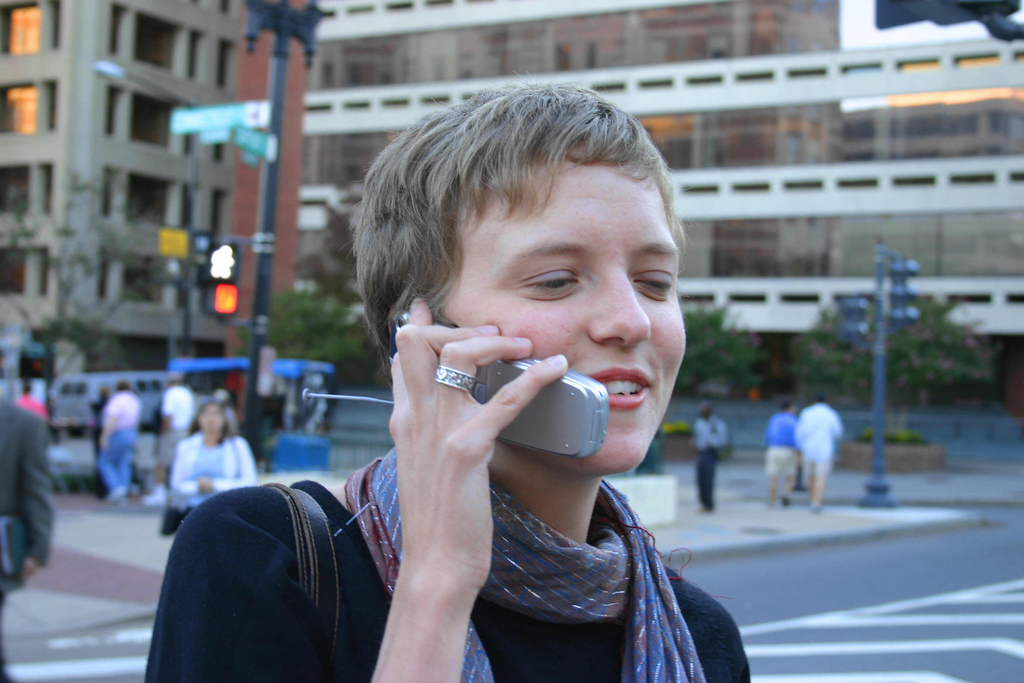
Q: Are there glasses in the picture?
A: No, there are no glasses.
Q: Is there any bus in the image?
A: Yes, there is a bus.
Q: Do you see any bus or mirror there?
A: Yes, there is a bus.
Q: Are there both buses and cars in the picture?
A: No, there is a bus but no cars.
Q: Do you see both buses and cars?
A: No, there is a bus but no cars.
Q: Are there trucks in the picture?
A: No, there are no trucks.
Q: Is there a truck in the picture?
A: No, there are no trucks.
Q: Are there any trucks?
A: No, there are no trucks.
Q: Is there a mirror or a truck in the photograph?
A: No, there are no trucks or mirrors.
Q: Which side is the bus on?
A: The bus is on the left of the image.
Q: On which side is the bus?
A: The bus is on the left of the image.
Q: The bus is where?
A: The bus is on the road.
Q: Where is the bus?
A: The bus is on the road.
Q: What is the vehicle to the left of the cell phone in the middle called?
A: The vehicle is a bus.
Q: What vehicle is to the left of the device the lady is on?
A: The vehicle is a bus.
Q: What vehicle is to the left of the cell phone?
A: The vehicle is a bus.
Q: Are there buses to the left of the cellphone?
A: Yes, there is a bus to the left of the cellphone.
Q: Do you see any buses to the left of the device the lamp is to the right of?
A: Yes, there is a bus to the left of the cellphone.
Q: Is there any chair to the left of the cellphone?
A: No, there is a bus to the left of the cellphone.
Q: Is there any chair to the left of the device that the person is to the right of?
A: No, there is a bus to the left of the cellphone.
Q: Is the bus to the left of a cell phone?
A: Yes, the bus is to the left of a cell phone.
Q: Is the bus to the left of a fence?
A: No, the bus is to the left of a cell phone.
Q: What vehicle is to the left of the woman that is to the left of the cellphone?
A: The vehicle is a bus.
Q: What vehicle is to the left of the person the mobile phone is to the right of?
A: The vehicle is a bus.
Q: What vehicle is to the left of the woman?
A: The vehicle is a bus.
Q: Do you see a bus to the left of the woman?
A: Yes, there is a bus to the left of the woman.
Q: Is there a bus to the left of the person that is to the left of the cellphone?
A: Yes, there is a bus to the left of the woman.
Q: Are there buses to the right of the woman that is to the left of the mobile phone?
A: No, the bus is to the left of the woman.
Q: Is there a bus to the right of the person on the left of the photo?
A: No, the bus is to the left of the woman.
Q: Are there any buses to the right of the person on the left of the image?
A: No, the bus is to the left of the woman.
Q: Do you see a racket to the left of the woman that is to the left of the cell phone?
A: No, there is a bus to the left of the woman.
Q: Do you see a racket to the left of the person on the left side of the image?
A: No, there is a bus to the left of the woman.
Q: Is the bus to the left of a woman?
A: Yes, the bus is to the left of a woman.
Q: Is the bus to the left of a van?
A: No, the bus is to the left of a woman.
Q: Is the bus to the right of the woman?
A: No, the bus is to the left of the woman.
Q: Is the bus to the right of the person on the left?
A: No, the bus is to the left of the woman.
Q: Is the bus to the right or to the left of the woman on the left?
A: The bus is to the left of the woman.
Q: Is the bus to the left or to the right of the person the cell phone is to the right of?
A: The bus is to the left of the woman.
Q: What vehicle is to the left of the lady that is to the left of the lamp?
A: The vehicle is a bus.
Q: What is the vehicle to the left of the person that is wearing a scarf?
A: The vehicle is a bus.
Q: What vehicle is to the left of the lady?
A: The vehicle is a bus.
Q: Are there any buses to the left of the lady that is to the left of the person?
A: Yes, there is a bus to the left of the lady.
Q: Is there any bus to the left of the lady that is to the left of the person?
A: Yes, there is a bus to the left of the lady.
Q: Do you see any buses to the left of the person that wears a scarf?
A: Yes, there is a bus to the left of the lady.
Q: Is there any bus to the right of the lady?
A: No, the bus is to the left of the lady.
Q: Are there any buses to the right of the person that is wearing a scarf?
A: No, the bus is to the left of the lady.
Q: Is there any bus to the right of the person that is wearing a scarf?
A: No, the bus is to the left of the lady.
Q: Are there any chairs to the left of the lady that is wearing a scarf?
A: No, there is a bus to the left of the lady.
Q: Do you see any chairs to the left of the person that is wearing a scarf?
A: No, there is a bus to the left of the lady.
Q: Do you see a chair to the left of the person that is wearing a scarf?
A: No, there is a bus to the left of the lady.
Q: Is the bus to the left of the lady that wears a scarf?
A: Yes, the bus is to the left of the lady.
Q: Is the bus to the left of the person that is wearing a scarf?
A: Yes, the bus is to the left of the lady.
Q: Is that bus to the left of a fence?
A: No, the bus is to the left of the lady.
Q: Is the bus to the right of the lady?
A: No, the bus is to the left of the lady.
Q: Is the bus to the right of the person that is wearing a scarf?
A: No, the bus is to the left of the lady.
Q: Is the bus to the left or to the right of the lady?
A: The bus is to the left of the lady.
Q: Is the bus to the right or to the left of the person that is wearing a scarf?
A: The bus is to the left of the lady.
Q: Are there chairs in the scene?
A: No, there are no chairs.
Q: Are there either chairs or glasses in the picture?
A: No, there are no chairs or glasses.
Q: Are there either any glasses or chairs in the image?
A: No, there are no chairs or glasses.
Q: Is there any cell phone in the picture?
A: Yes, there is a cell phone.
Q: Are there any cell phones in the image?
A: Yes, there is a cell phone.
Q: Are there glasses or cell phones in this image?
A: Yes, there is a cell phone.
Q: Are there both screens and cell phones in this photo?
A: No, there is a cell phone but no screens.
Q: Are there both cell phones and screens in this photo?
A: No, there is a cell phone but no screens.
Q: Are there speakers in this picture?
A: No, there are no speakers.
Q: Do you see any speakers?
A: No, there are no speakers.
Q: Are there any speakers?
A: No, there are no speakers.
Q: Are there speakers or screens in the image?
A: No, there are no speakers or screens.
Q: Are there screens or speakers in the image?
A: No, there are no speakers or screens.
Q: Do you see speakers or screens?
A: No, there are no speakers or screens.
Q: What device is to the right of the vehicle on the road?
A: The device is a cell phone.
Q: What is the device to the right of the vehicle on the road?
A: The device is a cell phone.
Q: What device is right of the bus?
A: The device is a cell phone.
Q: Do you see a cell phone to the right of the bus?
A: Yes, there is a cell phone to the right of the bus.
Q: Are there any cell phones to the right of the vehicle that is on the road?
A: Yes, there is a cell phone to the right of the bus.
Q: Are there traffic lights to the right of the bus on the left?
A: No, there is a cell phone to the right of the bus.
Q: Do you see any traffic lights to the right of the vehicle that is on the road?
A: No, there is a cell phone to the right of the bus.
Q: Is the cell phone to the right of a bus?
A: Yes, the cell phone is to the right of a bus.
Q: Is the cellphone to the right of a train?
A: No, the cellphone is to the right of a bus.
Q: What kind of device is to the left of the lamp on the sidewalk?
A: The device is a cell phone.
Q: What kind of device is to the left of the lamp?
A: The device is a cell phone.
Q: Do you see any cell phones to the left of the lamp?
A: Yes, there is a cell phone to the left of the lamp.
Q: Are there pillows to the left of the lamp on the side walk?
A: No, there is a cell phone to the left of the lamp.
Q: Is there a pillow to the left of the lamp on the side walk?
A: No, there is a cell phone to the left of the lamp.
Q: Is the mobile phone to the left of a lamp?
A: Yes, the mobile phone is to the left of a lamp.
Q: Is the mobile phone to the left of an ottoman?
A: No, the mobile phone is to the left of a lamp.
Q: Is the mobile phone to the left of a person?
A: Yes, the mobile phone is to the left of a person.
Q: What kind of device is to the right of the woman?
A: The device is a cell phone.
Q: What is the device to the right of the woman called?
A: The device is a cell phone.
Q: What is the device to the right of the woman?
A: The device is a cell phone.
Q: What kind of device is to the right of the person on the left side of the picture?
A: The device is a cell phone.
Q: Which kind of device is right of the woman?
A: The device is a cell phone.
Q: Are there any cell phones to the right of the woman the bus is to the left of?
A: Yes, there is a cell phone to the right of the woman.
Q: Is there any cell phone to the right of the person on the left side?
A: Yes, there is a cell phone to the right of the woman.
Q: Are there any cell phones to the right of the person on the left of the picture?
A: Yes, there is a cell phone to the right of the woman.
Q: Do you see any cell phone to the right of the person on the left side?
A: Yes, there is a cell phone to the right of the woman.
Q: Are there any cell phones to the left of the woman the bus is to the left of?
A: No, the cell phone is to the right of the woman.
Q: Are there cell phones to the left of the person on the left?
A: No, the cell phone is to the right of the woman.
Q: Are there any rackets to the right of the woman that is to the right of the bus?
A: No, there is a cell phone to the right of the woman.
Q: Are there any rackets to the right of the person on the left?
A: No, there is a cell phone to the right of the woman.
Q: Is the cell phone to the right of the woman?
A: Yes, the cell phone is to the right of the woman.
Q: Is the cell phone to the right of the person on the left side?
A: Yes, the cell phone is to the right of the woman.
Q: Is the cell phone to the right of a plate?
A: No, the cell phone is to the right of the woman.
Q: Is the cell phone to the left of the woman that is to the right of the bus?
A: No, the cell phone is to the right of the woman.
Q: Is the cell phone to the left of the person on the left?
A: No, the cell phone is to the right of the woman.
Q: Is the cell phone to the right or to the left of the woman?
A: The cell phone is to the right of the woman.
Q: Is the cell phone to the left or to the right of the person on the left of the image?
A: The cell phone is to the right of the woman.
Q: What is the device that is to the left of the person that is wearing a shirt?
A: The device is a cell phone.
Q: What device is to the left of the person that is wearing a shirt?
A: The device is a cell phone.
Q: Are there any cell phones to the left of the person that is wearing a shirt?
A: Yes, there is a cell phone to the left of the person.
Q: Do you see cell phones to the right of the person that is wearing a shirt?
A: No, the cell phone is to the left of the person.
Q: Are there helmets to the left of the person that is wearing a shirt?
A: No, there is a cell phone to the left of the person.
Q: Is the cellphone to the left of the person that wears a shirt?
A: Yes, the cellphone is to the left of the person.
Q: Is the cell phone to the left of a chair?
A: No, the cell phone is to the left of the person.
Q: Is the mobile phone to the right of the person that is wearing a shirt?
A: No, the mobile phone is to the left of the person.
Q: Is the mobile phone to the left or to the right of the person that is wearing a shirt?
A: The mobile phone is to the left of the person.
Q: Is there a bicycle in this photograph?
A: No, there are no bicycles.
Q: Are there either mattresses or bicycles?
A: No, there are no bicycles or mattresses.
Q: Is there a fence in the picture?
A: No, there are no fences.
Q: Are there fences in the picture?
A: No, there are no fences.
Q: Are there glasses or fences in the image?
A: No, there are no fences or glasses.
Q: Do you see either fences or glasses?
A: No, there are no fences or glasses.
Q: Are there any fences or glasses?
A: No, there are no fences or glasses.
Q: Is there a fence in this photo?
A: No, there are no fences.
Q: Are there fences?
A: No, there are no fences.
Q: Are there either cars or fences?
A: No, there are no fences or cars.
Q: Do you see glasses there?
A: No, there are no glasses.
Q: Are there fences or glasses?
A: No, there are no glasses or fences.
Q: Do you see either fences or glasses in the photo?
A: No, there are no glasses or fences.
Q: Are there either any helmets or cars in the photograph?
A: No, there are no cars or helmets.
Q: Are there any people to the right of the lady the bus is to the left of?
A: Yes, there is a person to the right of the lady.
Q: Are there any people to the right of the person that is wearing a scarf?
A: Yes, there is a person to the right of the lady.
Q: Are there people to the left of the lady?
A: No, the person is to the right of the lady.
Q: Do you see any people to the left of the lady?
A: No, the person is to the right of the lady.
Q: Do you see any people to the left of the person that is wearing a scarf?
A: No, the person is to the right of the lady.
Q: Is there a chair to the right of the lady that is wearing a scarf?
A: No, there is a person to the right of the lady.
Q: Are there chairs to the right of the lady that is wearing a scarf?
A: No, there is a person to the right of the lady.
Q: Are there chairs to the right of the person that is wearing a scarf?
A: No, there is a person to the right of the lady.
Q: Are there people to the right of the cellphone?
A: Yes, there is a person to the right of the cellphone.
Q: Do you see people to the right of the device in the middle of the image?
A: Yes, there is a person to the right of the cellphone.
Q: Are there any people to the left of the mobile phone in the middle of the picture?
A: No, the person is to the right of the mobile phone.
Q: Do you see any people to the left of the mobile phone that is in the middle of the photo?
A: No, the person is to the right of the mobile phone.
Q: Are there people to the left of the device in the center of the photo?
A: No, the person is to the right of the mobile phone.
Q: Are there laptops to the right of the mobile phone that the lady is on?
A: No, there is a person to the right of the mobile phone.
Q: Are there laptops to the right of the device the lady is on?
A: No, there is a person to the right of the mobile phone.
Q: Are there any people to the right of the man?
A: Yes, there is a person to the right of the man.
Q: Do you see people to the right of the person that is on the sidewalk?
A: Yes, there is a person to the right of the man.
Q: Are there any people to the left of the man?
A: No, the person is to the right of the man.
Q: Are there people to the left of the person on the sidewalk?
A: No, the person is to the right of the man.